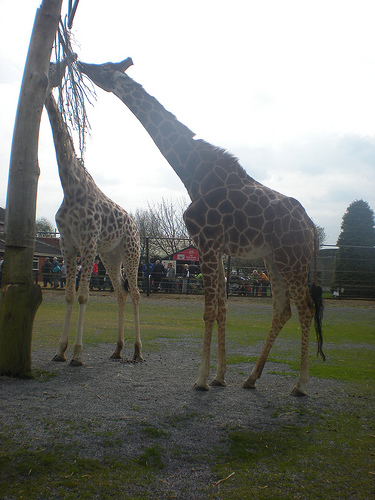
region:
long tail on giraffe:
[310, 223, 326, 361]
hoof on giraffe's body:
[69, 358, 86, 367]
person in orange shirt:
[257, 270, 268, 295]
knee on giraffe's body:
[76, 292, 87, 305]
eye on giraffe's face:
[101, 65, 109, 71]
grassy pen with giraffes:
[1, 290, 374, 498]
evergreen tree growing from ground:
[334, 199, 373, 298]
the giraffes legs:
[197, 254, 225, 396]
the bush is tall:
[345, 201, 370, 241]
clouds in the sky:
[266, 137, 366, 183]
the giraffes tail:
[311, 281, 330, 357]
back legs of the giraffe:
[249, 304, 313, 397]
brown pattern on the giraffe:
[75, 202, 118, 226]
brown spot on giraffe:
[201, 249, 215, 264]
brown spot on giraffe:
[201, 260, 213, 275]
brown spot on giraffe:
[202, 272, 211, 281]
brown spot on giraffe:
[205, 286, 216, 293]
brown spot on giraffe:
[273, 247, 288, 265]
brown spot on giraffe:
[292, 260, 300, 275]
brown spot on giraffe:
[231, 206, 247, 232]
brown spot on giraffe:
[202, 225, 224, 240]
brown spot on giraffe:
[184, 200, 207, 228]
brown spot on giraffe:
[302, 229, 315, 242]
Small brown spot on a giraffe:
[199, 219, 227, 240]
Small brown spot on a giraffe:
[220, 213, 235, 229]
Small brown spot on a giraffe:
[230, 206, 253, 233]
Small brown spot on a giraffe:
[243, 225, 254, 242]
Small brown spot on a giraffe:
[244, 210, 264, 228]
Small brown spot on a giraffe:
[226, 185, 249, 211]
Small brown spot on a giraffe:
[271, 245, 291, 273]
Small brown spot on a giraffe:
[275, 265, 293, 285]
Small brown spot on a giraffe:
[290, 285, 305, 306]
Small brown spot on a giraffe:
[239, 185, 265, 206]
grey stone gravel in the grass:
[4, 327, 370, 496]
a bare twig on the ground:
[215, 469, 235, 487]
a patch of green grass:
[141, 419, 173, 442]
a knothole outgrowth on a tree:
[30, 282, 40, 314]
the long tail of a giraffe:
[309, 225, 325, 362]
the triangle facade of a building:
[165, 241, 198, 261]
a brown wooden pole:
[143, 236, 150, 297]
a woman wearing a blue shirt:
[51, 261, 60, 288]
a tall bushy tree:
[333, 198, 373, 297]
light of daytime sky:
[0, 0, 370, 243]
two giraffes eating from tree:
[48, 56, 321, 395]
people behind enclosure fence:
[38, 258, 267, 290]